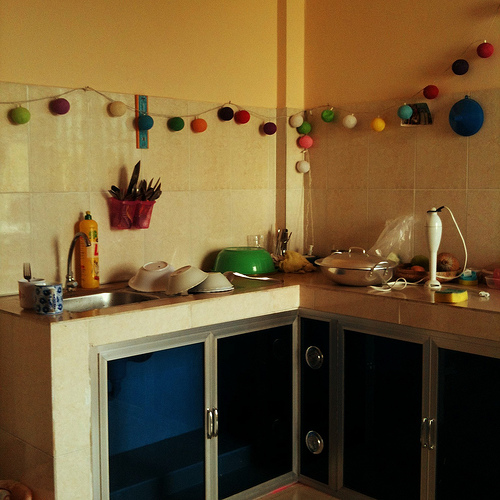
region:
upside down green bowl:
[209, 239, 279, 281]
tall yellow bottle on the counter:
[73, 209, 104, 291]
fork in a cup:
[21, 260, 33, 283]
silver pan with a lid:
[312, 238, 399, 295]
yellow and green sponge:
[433, 283, 470, 307]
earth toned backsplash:
[1, 80, 499, 296]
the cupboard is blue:
[214, 302, 306, 490]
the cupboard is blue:
[101, 348, 211, 492]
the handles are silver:
[208, 404, 224, 446]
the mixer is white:
[418, 180, 465, 302]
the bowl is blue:
[33, 278, 65, 314]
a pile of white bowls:
[124, 242, 232, 310]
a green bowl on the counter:
[213, 233, 273, 278]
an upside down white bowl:
[165, 261, 207, 296]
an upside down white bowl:
[129, 259, 174, 293]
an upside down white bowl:
[197, 267, 234, 292]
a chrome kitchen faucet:
[63, 230, 93, 293]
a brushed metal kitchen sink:
[58, 290, 153, 312]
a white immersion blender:
[424, 205, 443, 291]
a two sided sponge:
[432, 287, 469, 302]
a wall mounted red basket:
[104, 197, 153, 232]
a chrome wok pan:
[314, 245, 396, 285]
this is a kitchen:
[20, 11, 497, 498]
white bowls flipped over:
[129, 251, 237, 304]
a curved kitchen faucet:
[43, 217, 115, 286]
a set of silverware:
[100, 154, 177, 233]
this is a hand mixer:
[405, 183, 485, 302]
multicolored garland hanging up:
[11, 6, 498, 182]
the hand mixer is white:
[411, 188, 467, 301]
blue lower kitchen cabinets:
[83, 325, 305, 497]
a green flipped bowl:
[210, 222, 280, 297]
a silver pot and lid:
[303, 234, 400, 291]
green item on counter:
[191, 228, 291, 290]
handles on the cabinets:
[180, 389, 252, 458]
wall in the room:
[173, 154, 245, 203]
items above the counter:
[77, 53, 463, 165]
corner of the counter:
[13, 295, 94, 365]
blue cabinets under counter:
[45, 314, 315, 497]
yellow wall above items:
[100, 5, 251, 57]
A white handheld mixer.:
[419, 203, 446, 295]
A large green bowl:
[215, 245, 275, 275]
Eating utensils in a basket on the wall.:
[106, 160, 160, 240]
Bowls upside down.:
[130, 255, 239, 296]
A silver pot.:
[307, 250, 399, 288]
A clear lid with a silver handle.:
[324, 247, 389, 269]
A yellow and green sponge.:
[439, 284, 470, 306]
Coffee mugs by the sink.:
[15, 271, 69, 316]